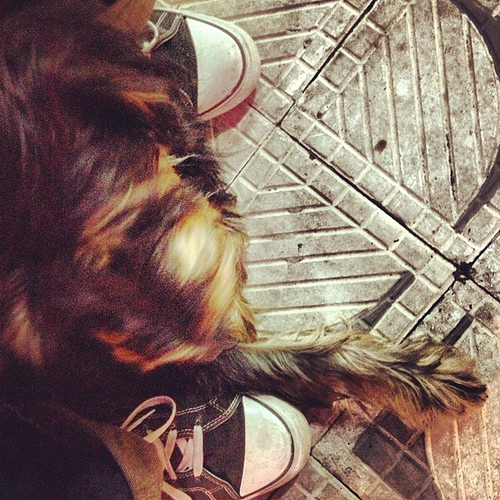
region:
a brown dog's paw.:
[235, 325, 483, 394]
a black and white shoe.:
[83, 383, 323, 498]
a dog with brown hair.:
[4, 12, 283, 386]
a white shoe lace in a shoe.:
[113, 365, 217, 494]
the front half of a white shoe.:
[181, 8, 272, 121]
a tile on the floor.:
[273, 0, 498, 270]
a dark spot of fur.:
[39, 95, 143, 230]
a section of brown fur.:
[161, 206, 227, 286]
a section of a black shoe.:
[216, 418, 227, 479]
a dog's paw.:
[384, 345, 486, 439]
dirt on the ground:
[305, 95, 496, 287]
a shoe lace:
[127, 400, 172, 431]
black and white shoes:
[182, 405, 299, 494]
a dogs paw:
[353, 323, 468, 430]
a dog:
[5, 98, 245, 361]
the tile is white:
[252, 160, 416, 300]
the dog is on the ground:
[32, 103, 244, 345]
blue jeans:
[10, 400, 99, 498]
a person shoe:
[149, 16, 253, 99]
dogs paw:
[327, 331, 481, 423]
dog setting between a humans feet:
[6, 2, 484, 442]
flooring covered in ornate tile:
[187, 5, 494, 498]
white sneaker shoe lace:
[128, 395, 205, 494]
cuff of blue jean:
[33, 394, 163, 499]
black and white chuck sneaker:
[152, 392, 304, 498]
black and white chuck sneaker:
[143, 11, 258, 116]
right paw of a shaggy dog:
[286, 331, 486, 434]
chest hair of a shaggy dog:
[157, 168, 252, 352]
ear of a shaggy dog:
[77, 45, 182, 134]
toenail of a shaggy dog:
[480, 390, 490, 400]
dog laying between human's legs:
[2, 1, 487, 496]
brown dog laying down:
[6, 20, 494, 416]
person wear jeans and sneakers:
[8, 373, 315, 496]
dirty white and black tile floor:
[265, 5, 499, 499]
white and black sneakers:
[83, 5, 316, 499]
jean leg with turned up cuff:
[1, 395, 170, 498]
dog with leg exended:
[3, 42, 486, 422]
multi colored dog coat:
[6, 12, 498, 416]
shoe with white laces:
[88, 386, 314, 496]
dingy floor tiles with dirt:
[270, 30, 498, 356]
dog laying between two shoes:
[6, 7, 479, 412]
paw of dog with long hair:
[295, 314, 477, 431]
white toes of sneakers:
[190, 18, 297, 496]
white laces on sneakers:
[140, 18, 229, 499]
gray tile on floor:
[213, 17, 495, 499]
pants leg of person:
[16, 402, 159, 499]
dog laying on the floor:
[10, 15, 498, 463]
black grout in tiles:
[257, 93, 481, 343]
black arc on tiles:
[350, 333, 484, 495]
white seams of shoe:
[162, 405, 238, 497]